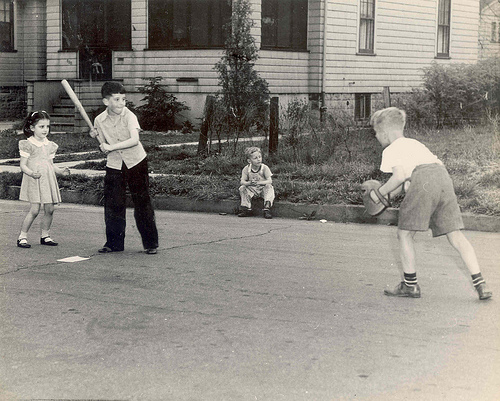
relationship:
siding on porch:
[258, 48, 306, 57] [56, 41, 315, 91]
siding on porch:
[113, 51, 308, 94] [56, 41, 315, 91]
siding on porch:
[112, 62, 234, 72] [56, 41, 315, 91]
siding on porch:
[113, 51, 308, 94] [3, 17, 360, 100]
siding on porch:
[113, 51, 308, 94] [147, 69, 253, 131]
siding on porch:
[113, 51, 308, 94] [10, 10, 294, 130]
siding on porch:
[255, 64, 309, 70] [259, 58, 308, 87]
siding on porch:
[261, 68, 303, 73] [267, 54, 293, 84]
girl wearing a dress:
[16, 108, 61, 250] [17, 136, 61, 203]